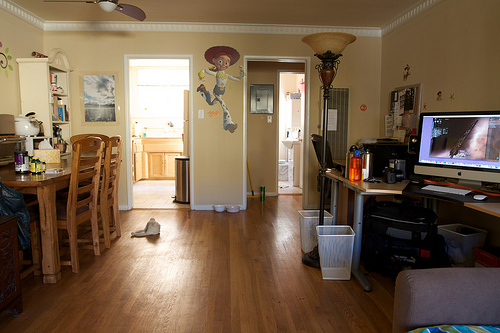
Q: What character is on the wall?
A: Jessie.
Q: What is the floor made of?
A: Wood.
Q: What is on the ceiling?
A: Fan.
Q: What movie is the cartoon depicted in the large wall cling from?
A: Toy Story 2.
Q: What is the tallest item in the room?
A: Lamp.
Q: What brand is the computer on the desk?
A: Apple.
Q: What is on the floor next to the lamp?
A: White wastebaskets.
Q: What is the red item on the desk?
A: Water bottle.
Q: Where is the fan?
A: Ceiling.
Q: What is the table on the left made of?
A: Wood.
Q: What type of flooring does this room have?
A: Hardwood.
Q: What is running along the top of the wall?
A: Crown molding.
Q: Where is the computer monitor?
A: On the desk.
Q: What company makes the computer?
A: Apple.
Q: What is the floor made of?
A: Hardwood.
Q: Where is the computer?
A: Desk.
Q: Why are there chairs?
A: To sit.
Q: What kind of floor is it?
A: Wood.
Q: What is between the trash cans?
A: Floor lamp.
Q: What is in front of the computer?
A: Keyboard.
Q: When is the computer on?
A: Now.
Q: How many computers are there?
A: One.